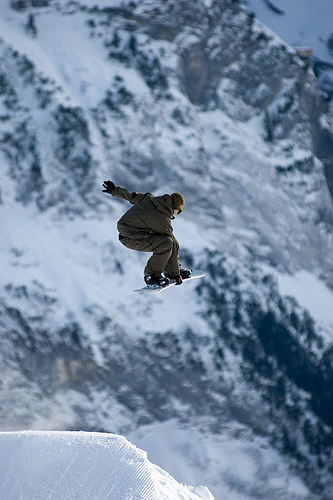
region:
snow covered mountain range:
[60, 49, 236, 125]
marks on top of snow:
[81, 427, 162, 485]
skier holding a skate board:
[82, 172, 226, 314]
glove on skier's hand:
[91, 173, 119, 195]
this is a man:
[87, 163, 197, 284]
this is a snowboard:
[136, 260, 206, 296]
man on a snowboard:
[88, 154, 210, 302]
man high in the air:
[19, 106, 302, 469]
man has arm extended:
[93, 169, 145, 206]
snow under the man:
[13, 400, 212, 498]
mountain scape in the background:
[3, 12, 331, 481]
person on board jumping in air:
[78, 153, 206, 294]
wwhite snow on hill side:
[180, 425, 211, 456]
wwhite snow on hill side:
[238, 370, 278, 404]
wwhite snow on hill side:
[155, 360, 201, 405]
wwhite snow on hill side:
[26, 372, 58, 402]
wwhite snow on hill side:
[41, 249, 70, 289]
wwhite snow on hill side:
[78, 459, 102, 473]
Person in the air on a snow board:
[103, 173, 217, 308]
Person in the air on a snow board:
[89, 166, 214, 298]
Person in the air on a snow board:
[92, 168, 231, 311]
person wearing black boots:
[142, 265, 190, 288]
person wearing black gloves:
[101, 177, 111, 193]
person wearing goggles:
[175, 200, 187, 215]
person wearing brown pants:
[120, 230, 179, 273]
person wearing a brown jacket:
[110, 181, 174, 236]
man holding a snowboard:
[166, 263, 187, 286]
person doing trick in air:
[92, 157, 204, 298]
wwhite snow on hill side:
[71, 283, 110, 330]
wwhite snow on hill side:
[231, 414, 267, 450]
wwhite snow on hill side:
[71, 396, 90, 421]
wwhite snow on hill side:
[41, 176, 60, 198]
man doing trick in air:
[86, 167, 193, 296]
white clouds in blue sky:
[23, 18, 87, 62]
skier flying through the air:
[94, 163, 210, 294]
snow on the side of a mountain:
[60, 273, 111, 316]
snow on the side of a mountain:
[299, 278, 329, 310]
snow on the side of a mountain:
[163, 434, 196, 470]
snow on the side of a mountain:
[35, 143, 80, 186]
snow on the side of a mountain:
[266, 371, 296, 404]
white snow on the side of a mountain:
[210, 478, 236, 489]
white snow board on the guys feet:
[141, 269, 223, 296]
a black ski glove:
[102, 177, 117, 199]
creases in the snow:
[6, 426, 156, 497]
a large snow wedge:
[5, 420, 209, 498]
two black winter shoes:
[143, 268, 199, 291]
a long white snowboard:
[136, 268, 204, 299]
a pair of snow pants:
[117, 230, 183, 277]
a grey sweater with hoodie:
[114, 184, 177, 245]